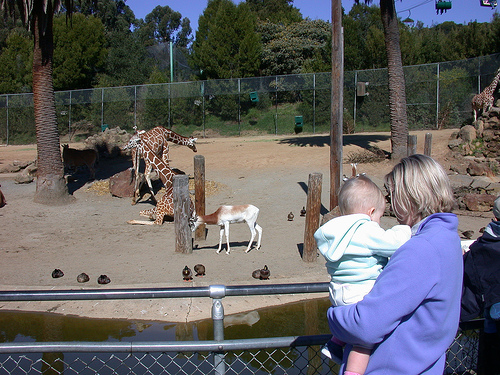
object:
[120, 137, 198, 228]
giraffe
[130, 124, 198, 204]
giraffe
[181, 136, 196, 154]
head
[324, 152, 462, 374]
mother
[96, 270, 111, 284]
duck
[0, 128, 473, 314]
ground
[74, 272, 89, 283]
duck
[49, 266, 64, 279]
duck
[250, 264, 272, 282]
duck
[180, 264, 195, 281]
duck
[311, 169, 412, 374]
baby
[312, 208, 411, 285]
hoodie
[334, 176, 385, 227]
head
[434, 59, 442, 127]
pole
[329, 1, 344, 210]
post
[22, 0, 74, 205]
tree trunk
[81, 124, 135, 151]
rock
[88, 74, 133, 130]
tree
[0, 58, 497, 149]
fence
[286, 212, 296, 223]
bird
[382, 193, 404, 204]
glasses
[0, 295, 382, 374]
water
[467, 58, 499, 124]
giraffe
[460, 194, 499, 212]
rocks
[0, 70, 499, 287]
animal area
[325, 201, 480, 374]
jacket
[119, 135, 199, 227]
animal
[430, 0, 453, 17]
lift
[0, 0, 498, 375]
background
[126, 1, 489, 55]
sky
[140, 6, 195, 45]
trees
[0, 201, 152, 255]
dirt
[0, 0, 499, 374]
zoo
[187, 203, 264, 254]
deer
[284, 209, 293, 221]
pigeons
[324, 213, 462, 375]
sweater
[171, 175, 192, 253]
tree trunk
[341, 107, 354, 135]
trees